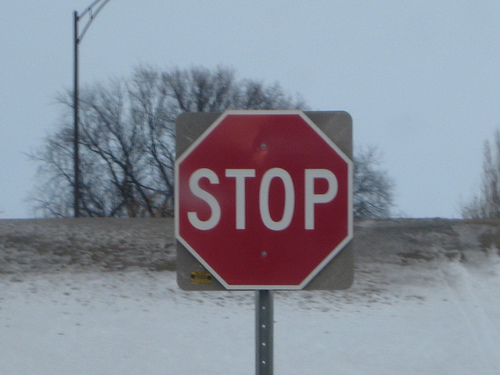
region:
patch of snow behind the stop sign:
[39, 271, 214, 370]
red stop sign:
[152, 101, 387, 323]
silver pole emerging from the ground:
[234, 283, 293, 373]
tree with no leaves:
[49, 56, 407, 230]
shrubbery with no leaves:
[461, 136, 498, 212]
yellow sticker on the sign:
[181, 256, 223, 297]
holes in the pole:
[257, 301, 271, 315]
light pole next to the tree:
[67, 6, 102, 223]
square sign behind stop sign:
[158, 99, 373, 295]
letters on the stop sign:
[185, 165, 343, 239]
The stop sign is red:
[173, 108, 354, 292]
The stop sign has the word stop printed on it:
[171, 106, 356, 294]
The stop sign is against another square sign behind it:
[173, 107, 356, 296]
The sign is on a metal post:
[252, 287, 277, 374]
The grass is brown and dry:
[0, 213, 499, 284]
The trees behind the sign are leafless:
[20, 55, 397, 222]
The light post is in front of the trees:
[70, 0, 113, 215]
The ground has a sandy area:
[0, 254, 498, 373]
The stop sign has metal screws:
[256, 132, 270, 266]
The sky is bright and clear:
[0, 0, 497, 220]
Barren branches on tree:
[77, 86, 164, 208]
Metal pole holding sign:
[244, 293, 290, 370]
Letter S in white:
[187, 165, 222, 230]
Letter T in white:
[224, 169, 258, 231]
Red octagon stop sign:
[177, 112, 353, 286]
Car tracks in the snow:
[424, 243, 496, 374]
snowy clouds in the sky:
[357, 45, 493, 132]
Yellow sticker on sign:
[184, 267, 213, 287]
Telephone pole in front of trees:
[62, 29, 91, 214]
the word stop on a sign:
[188, 164, 337, 239]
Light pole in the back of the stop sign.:
[68, 1, 108, 218]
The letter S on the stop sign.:
[188, 163, 225, 236]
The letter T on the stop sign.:
[224, 161, 259, 233]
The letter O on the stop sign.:
[260, 164, 295, 236]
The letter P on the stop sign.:
[303, 163, 336, 238]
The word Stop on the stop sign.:
[186, 160, 338, 242]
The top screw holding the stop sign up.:
[253, 137, 274, 157]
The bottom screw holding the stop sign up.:
[251, 250, 268, 262]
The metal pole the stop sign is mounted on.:
[256, 289, 279, 372]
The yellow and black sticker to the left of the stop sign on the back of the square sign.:
[189, 263, 211, 288]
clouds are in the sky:
[341, 35, 398, 125]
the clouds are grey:
[382, 95, 419, 156]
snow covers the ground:
[378, 253, 433, 344]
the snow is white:
[382, 282, 429, 341]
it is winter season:
[3, 67, 498, 373]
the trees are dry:
[58, 82, 216, 311]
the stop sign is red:
[125, 84, 411, 326]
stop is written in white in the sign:
[166, 127, 380, 302]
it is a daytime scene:
[21, 68, 446, 373]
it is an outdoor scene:
[26, 67, 488, 362]